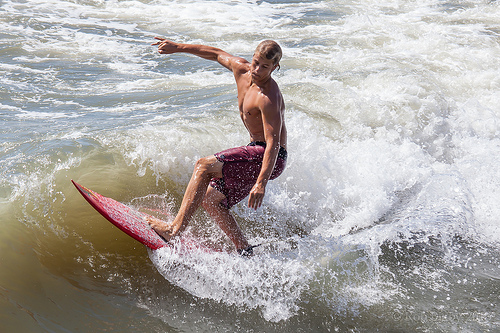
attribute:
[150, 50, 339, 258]
surfer — on surf board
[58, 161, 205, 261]
sufboard — red